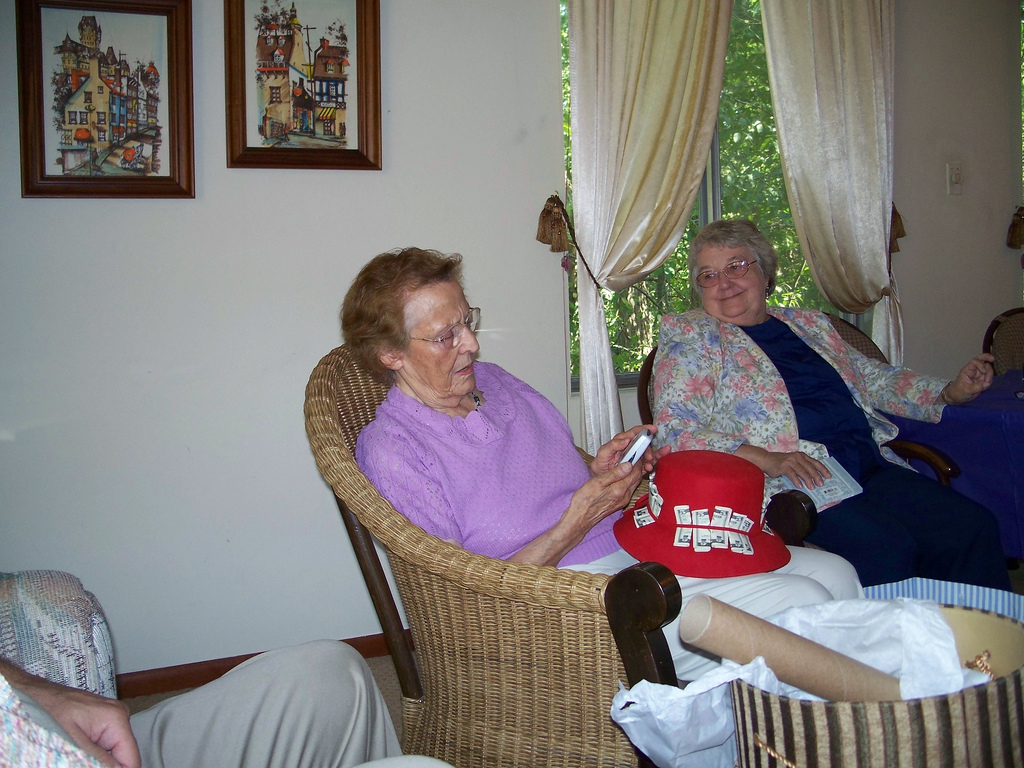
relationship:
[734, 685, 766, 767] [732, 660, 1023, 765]
stripe on bag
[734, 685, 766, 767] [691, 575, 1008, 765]
stripe on bag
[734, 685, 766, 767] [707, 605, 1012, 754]
stripe on bag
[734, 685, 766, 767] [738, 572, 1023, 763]
stripe on bag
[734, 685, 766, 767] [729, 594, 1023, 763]
stripe on bag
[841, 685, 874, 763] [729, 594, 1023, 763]
stripe on bag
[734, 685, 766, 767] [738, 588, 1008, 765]
stripe on bag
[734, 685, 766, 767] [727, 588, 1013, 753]
stripe on bag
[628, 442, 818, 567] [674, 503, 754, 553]
hat with band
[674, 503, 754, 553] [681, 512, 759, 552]
band in band